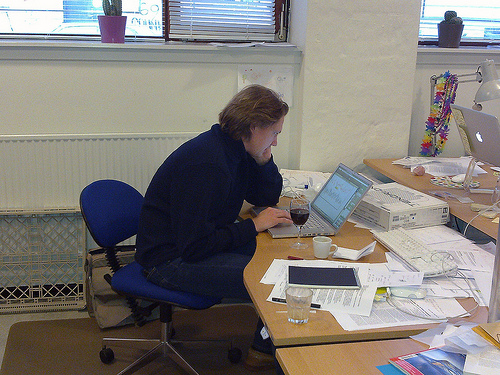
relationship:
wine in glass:
[287, 206, 310, 227] [288, 195, 311, 252]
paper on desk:
[420, 227, 491, 281] [225, 164, 499, 352]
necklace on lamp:
[426, 73, 456, 161] [419, 59, 499, 157]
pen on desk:
[271, 296, 323, 311] [225, 164, 499, 352]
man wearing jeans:
[119, 73, 282, 365] [133, 247, 280, 350]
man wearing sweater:
[119, 73, 282, 365] [137, 125, 282, 271]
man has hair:
[119, 73, 282, 365] [217, 82, 288, 139]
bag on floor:
[77, 243, 162, 333] [3, 292, 286, 374]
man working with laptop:
[119, 73, 282, 365] [247, 160, 373, 241]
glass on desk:
[288, 195, 311, 252] [225, 164, 499, 352]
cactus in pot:
[101, 1, 126, 17] [97, 16, 130, 44]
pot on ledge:
[97, 16, 130, 44] [1, 38, 300, 66]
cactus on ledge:
[101, 1, 126, 17] [1, 38, 300, 66]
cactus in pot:
[439, 8, 466, 26] [433, 22, 464, 48]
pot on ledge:
[433, 22, 464, 48] [408, 42, 499, 63]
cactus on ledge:
[439, 8, 466, 26] [408, 42, 499, 63]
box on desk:
[353, 180, 455, 231] [225, 164, 499, 352]